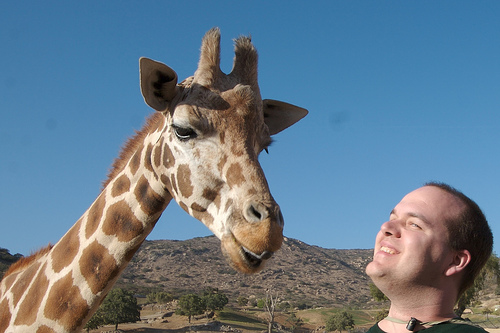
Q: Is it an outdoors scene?
A: Yes, it is outdoors.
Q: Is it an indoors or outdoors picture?
A: It is outdoors.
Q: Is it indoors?
A: No, it is outdoors.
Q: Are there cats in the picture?
A: No, there are no cats.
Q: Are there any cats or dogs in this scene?
A: No, there are no cats or dogs.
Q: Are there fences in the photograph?
A: No, there are no fences.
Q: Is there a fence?
A: No, there are no fences.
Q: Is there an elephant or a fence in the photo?
A: No, there are no fences or elephants.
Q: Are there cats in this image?
A: No, there are no cats.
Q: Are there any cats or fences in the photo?
A: No, there are no cats or fences.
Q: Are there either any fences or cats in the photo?
A: No, there are no cats or fences.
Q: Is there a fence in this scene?
A: No, there are no fences.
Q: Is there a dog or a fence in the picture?
A: No, there are no fences or dogs.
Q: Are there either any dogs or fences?
A: No, there are no fences or dogs.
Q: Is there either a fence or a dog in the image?
A: No, there are no fences or dogs.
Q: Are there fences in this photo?
A: No, there are no fences.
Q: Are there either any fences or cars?
A: No, there are no fences or cars.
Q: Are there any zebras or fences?
A: No, there are no fences or zebras.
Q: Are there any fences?
A: No, there are no fences.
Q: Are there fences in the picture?
A: No, there are no fences.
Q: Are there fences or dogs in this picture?
A: No, there are no fences or dogs.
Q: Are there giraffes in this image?
A: Yes, there is a giraffe.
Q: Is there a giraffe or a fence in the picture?
A: Yes, there is a giraffe.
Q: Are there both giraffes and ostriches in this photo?
A: No, there is a giraffe but no ostriches.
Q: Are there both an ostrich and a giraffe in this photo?
A: No, there is a giraffe but no ostriches.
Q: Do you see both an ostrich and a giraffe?
A: No, there is a giraffe but no ostriches.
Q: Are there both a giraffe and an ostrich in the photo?
A: No, there is a giraffe but no ostriches.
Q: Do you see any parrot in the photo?
A: No, there are no parrots.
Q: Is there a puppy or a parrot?
A: No, there are no parrots or puppys.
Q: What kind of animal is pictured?
A: The animal is a giraffe.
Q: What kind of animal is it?
A: The animal is a giraffe.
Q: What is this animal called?
A: This is a giraffe.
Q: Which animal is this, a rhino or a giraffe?
A: This is a giraffe.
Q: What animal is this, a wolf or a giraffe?
A: This is a giraffe.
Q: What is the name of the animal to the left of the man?
A: The animal is a giraffe.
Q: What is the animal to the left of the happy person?
A: The animal is a giraffe.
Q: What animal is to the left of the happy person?
A: The animal is a giraffe.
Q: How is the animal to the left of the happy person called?
A: The animal is a giraffe.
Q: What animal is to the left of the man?
A: The animal is a giraffe.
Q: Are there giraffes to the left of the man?
A: Yes, there is a giraffe to the left of the man.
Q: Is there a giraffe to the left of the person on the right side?
A: Yes, there is a giraffe to the left of the man.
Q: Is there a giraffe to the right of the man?
A: No, the giraffe is to the left of the man.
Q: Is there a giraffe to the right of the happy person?
A: No, the giraffe is to the left of the man.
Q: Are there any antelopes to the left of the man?
A: No, there is a giraffe to the left of the man.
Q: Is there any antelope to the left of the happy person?
A: No, there is a giraffe to the left of the man.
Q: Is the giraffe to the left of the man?
A: Yes, the giraffe is to the left of the man.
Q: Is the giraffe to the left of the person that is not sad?
A: Yes, the giraffe is to the left of the man.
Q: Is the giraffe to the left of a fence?
A: No, the giraffe is to the left of the man.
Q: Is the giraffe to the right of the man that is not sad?
A: No, the giraffe is to the left of the man.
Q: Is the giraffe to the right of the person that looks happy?
A: No, the giraffe is to the left of the man.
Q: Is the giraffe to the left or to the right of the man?
A: The giraffe is to the left of the man.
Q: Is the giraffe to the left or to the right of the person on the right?
A: The giraffe is to the left of the man.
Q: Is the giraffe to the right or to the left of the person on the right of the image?
A: The giraffe is to the left of the man.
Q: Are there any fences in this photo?
A: No, there are no fences.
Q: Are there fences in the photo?
A: No, there are no fences.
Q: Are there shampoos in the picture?
A: No, there are no shampoos.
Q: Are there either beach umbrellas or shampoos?
A: No, there are no shampoos or beach umbrellas.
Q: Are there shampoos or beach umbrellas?
A: No, there are no shampoos or beach umbrellas.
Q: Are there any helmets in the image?
A: No, there are no helmets.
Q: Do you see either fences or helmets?
A: No, there are no helmets or fences.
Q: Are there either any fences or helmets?
A: No, there are no helmets or fences.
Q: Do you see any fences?
A: No, there are no fences.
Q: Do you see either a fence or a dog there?
A: No, there are no fences or dogs.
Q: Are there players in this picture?
A: No, there are no players.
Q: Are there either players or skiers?
A: No, there are no players or skiers.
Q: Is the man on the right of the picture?
A: Yes, the man is on the right of the image.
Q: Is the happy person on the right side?
A: Yes, the man is on the right of the image.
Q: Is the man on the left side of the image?
A: No, the man is on the right of the image.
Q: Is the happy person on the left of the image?
A: No, the man is on the right of the image.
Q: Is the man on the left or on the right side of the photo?
A: The man is on the right of the image.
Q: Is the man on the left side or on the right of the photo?
A: The man is on the right of the image.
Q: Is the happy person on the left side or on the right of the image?
A: The man is on the right of the image.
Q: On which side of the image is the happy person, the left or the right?
A: The man is on the right of the image.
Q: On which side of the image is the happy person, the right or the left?
A: The man is on the right of the image.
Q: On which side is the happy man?
A: The man is on the right of the image.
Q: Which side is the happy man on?
A: The man is on the right of the image.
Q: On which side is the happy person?
A: The man is on the right of the image.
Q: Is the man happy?
A: Yes, the man is happy.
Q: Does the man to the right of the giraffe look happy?
A: Yes, the man is happy.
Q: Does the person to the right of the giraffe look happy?
A: Yes, the man is happy.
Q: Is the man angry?
A: No, the man is happy.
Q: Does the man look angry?
A: No, the man is happy.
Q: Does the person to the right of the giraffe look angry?
A: No, the man is happy.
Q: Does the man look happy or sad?
A: The man is happy.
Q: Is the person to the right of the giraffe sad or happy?
A: The man is happy.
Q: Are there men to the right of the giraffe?
A: Yes, there is a man to the right of the giraffe.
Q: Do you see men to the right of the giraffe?
A: Yes, there is a man to the right of the giraffe.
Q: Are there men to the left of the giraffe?
A: No, the man is to the right of the giraffe.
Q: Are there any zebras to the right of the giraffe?
A: No, there is a man to the right of the giraffe.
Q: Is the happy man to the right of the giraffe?
A: Yes, the man is to the right of the giraffe.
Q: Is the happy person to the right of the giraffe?
A: Yes, the man is to the right of the giraffe.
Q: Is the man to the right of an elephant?
A: No, the man is to the right of the giraffe.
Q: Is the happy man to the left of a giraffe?
A: No, the man is to the right of a giraffe.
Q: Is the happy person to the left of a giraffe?
A: No, the man is to the right of a giraffe.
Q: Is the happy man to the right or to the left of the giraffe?
A: The man is to the right of the giraffe.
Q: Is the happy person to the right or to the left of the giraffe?
A: The man is to the right of the giraffe.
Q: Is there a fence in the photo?
A: No, there are no fences.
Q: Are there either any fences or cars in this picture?
A: No, there are no fences or cars.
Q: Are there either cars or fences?
A: No, there are no fences or cars.